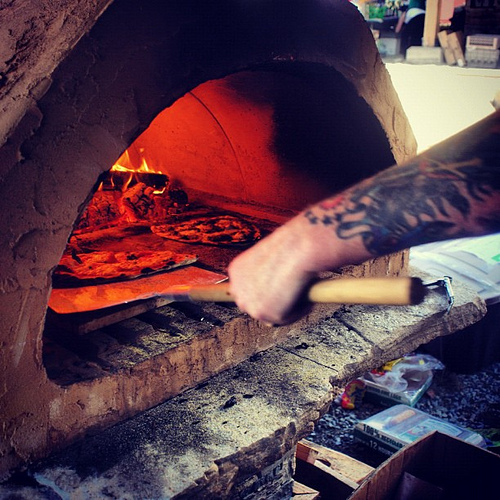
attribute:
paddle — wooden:
[47, 267, 422, 340]